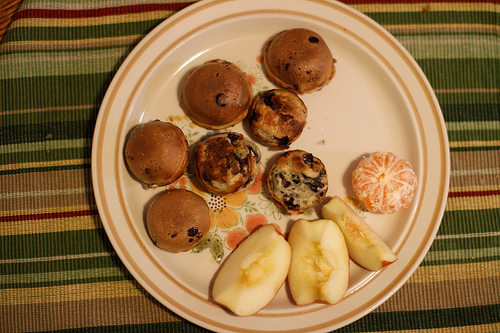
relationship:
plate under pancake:
[90, 0, 450, 332] [264, 28, 338, 95]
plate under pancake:
[90, 0, 450, 332] [180, 59, 253, 131]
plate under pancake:
[90, 0, 450, 332] [248, 88, 308, 150]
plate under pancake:
[90, 0, 450, 332] [193, 132, 261, 195]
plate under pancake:
[90, 0, 450, 332] [267, 149, 328, 215]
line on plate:
[97, 0, 447, 332] [90, 0, 450, 332]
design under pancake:
[165, 54, 368, 265] [264, 28, 338, 95]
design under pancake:
[165, 54, 368, 265] [180, 59, 253, 131]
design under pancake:
[165, 54, 368, 265] [248, 88, 308, 150]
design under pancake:
[165, 54, 368, 265] [193, 132, 261, 195]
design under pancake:
[165, 54, 368, 265] [267, 149, 328, 215]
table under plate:
[0, 0, 22, 44] [90, 0, 450, 332]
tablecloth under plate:
[1, 0, 500, 333] [90, 0, 450, 332]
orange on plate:
[351, 151, 418, 214] [90, 0, 450, 332]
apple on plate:
[211, 224, 292, 316] [90, 0, 450, 332]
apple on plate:
[287, 218, 350, 305] [90, 0, 450, 332]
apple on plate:
[320, 195, 398, 272] [90, 0, 450, 332]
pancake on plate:
[267, 149, 328, 215] [90, 0, 450, 332]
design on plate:
[165, 54, 368, 265] [90, 0, 450, 332]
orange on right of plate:
[351, 151, 418, 214] [90, 0, 450, 332]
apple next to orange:
[320, 195, 398, 272] [351, 151, 418, 214]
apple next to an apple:
[287, 218, 350, 305] [211, 224, 292, 316]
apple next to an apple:
[287, 218, 350, 305] [320, 195, 398, 272]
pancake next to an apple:
[267, 149, 328, 215] [211, 224, 292, 316]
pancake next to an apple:
[267, 149, 328, 215] [287, 218, 350, 305]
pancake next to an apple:
[267, 149, 328, 215] [320, 195, 398, 272]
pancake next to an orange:
[267, 149, 328, 215] [351, 151, 418, 214]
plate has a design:
[90, 0, 450, 332] [165, 54, 368, 265]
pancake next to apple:
[267, 149, 328, 215] [211, 224, 292, 316]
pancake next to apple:
[267, 149, 328, 215] [287, 218, 350, 305]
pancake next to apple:
[267, 149, 328, 215] [320, 195, 398, 272]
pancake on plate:
[264, 28, 338, 95] [90, 0, 450, 332]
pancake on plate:
[180, 59, 253, 131] [90, 0, 450, 332]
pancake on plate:
[248, 88, 308, 150] [90, 0, 450, 332]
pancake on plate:
[193, 132, 261, 195] [90, 0, 450, 332]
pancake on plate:
[125, 119, 190, 188] [90, 0, 450, 332]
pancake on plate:
[147, 189, 211, 254] [90, 0, 450, 332]